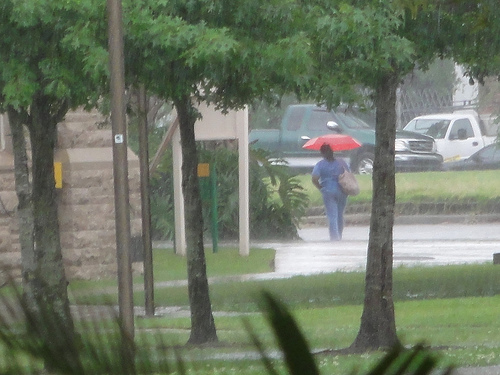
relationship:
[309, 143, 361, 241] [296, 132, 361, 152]
woman holds umbrella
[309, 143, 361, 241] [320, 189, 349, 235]
woman wears pants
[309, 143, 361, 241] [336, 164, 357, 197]
woman carrying bag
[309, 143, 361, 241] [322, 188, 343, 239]
woman wearing pants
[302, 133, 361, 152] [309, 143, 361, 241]
red umbrella over woman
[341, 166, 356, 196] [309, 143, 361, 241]
purse on woman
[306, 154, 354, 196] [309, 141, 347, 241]
shirt on woman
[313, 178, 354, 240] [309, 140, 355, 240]
jeans on woman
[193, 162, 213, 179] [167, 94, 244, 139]
sign under sign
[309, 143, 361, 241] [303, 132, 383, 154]
woman carrying umbrella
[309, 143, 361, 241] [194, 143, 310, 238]
woman walking past palm trees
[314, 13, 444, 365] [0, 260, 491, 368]
trees in grass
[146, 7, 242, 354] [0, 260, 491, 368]
trees in grass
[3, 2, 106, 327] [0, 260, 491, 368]
trees in grass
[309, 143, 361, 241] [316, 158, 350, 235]
woman wearing outfit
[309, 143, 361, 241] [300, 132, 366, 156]
woman carrying umbrella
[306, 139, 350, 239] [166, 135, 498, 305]
woman walking in park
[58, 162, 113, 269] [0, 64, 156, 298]
wall on building